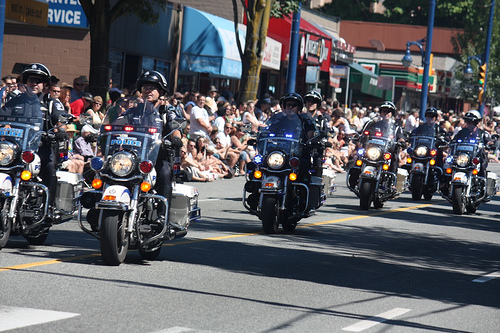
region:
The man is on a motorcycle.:
[0, 58, 84, 260]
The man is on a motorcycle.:
[73, 60, 210, 269]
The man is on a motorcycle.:
[238, 84, 340, 239]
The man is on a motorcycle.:
[343, 88, 412, 218]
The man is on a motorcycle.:
[403, 90, 446, 208]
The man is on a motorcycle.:
[441, 96, 499, 224]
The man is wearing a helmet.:
[0, 57, 86, 257]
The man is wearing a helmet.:
[73, 62, 213, 267]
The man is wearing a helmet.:
[230, 72, 340, 237]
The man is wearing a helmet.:
[343, 85, 410, 211]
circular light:
[258, 149, 289, 169]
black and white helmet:
[135, 65, 162, 82]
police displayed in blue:
[97, 136, 147, 149]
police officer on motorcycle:
[253, 89, 331, 255]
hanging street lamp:
[399, 36, 425, 78]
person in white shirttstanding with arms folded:
[189, 87, 215, 133]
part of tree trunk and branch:
[230, 14, 258, 61]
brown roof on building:
[353, 20, 404, 54]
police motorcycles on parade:
[13, 8, 484, 310]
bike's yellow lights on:
[242, 165, 299, 181]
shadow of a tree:
[345, 216, 486, 267]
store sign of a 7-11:
[360, 56, 435, 87]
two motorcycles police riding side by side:
[0, 55, 197, 266]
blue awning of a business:
[181, 5, 243, 76]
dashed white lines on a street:
[337, 235, 497, 330]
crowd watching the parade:
[185, 80, 242, 182]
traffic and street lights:
[460, 51, 490, 102]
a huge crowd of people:
[15, 30, 499, 255]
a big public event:
[7, 40, 479, 247]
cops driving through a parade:
[21, 56, 496, 237]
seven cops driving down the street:
[5, 50, 498, 234]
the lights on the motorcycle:
[2, 129, 483, 193]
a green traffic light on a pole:
[470, 57, 491, 90]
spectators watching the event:
[189, 85, 251, 167]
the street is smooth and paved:
[30, 255, 483, 327]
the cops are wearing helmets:
[15, 46, 492, 127]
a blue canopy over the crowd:
[150, 5, 255, 93]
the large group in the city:
[0, 61, 499, 263]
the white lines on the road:
[0, 196, 499, 331]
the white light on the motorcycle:
[266, 153, 283, 169]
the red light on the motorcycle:
[138, 160, 153, 172]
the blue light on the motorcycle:
[89, 158, 103, 170]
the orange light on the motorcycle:
[140, 180, 149, 190]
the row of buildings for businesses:
[0, 0, 499, 115]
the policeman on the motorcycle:
[97, 70, 182, 225]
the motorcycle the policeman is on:
[72, 95, 200, 265]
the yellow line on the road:
[0, 189, 499, 271]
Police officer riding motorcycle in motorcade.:
[79, 64, 203, 269]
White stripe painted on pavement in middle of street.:
[332, 301, 413, 331]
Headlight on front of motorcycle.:
[261, 149, 288, 175]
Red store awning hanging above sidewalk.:
[243, 1, 334, 73]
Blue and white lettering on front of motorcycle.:
[109, 130, 141, 150]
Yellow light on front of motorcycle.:
[135, 174, 154, 198]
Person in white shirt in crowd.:
[213, 122, 240, 174]